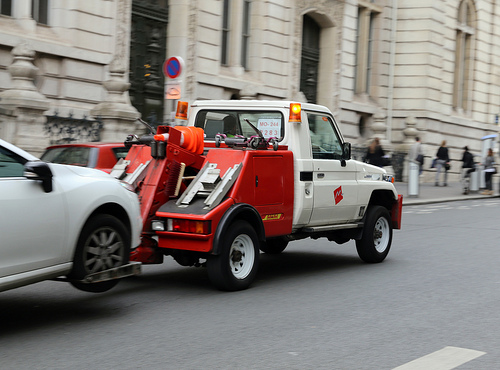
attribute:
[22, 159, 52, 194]
mirror — rearview 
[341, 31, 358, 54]
stone — white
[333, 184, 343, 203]
logo — red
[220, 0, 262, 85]
windows — thin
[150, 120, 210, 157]
cones — orange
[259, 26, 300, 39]
stone — white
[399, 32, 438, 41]
stone — white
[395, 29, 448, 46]
stone — white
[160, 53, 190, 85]
sign — red stop  , Blue 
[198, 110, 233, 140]
window — Small 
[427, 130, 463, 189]
girl — sexy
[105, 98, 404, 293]
truck — red, white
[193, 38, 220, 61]
stone — white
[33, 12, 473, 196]
building — white stone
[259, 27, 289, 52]
stone — white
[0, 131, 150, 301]
car — white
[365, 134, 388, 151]
hair — blonde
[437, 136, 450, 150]
hair — blonde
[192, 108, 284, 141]
window — small